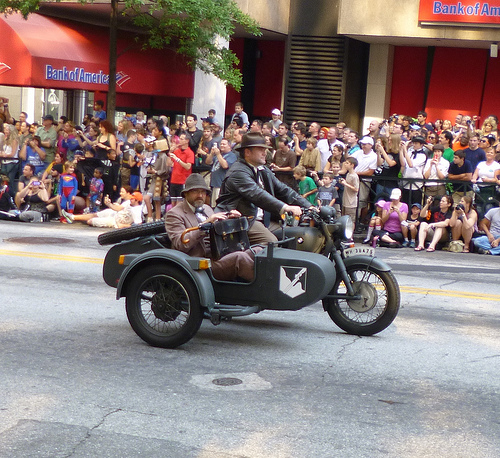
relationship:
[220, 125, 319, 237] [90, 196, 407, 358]
man riding motorcycle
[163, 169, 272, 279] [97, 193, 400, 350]
man sitting in motorcycle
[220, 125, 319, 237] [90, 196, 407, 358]
man driving motorcycle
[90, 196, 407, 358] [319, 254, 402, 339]
motorcycle has front tire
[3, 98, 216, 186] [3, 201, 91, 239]
people standing on street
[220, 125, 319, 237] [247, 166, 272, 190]
man wearing shirt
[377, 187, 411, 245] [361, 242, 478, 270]
person sitting on ground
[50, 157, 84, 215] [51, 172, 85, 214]
child in superman outfit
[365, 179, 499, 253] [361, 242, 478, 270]
people sitting on ground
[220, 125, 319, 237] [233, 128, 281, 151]
man wearing fedora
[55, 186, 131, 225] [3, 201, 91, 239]
man legs on road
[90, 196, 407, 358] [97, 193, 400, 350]
motorcycle with motorcycle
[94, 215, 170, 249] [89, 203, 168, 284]
wheel on back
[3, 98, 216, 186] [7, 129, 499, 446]
people waiting to watch event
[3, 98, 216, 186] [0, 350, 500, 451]
people besides asphalt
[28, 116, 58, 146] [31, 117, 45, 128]
people holding camera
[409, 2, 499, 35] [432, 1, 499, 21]
board displaying name of a bank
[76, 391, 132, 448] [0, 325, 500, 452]
crack in asphalt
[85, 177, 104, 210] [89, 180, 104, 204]
costume of superman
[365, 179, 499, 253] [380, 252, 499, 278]
family sitting on curb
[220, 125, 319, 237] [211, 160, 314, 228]
man with jacket